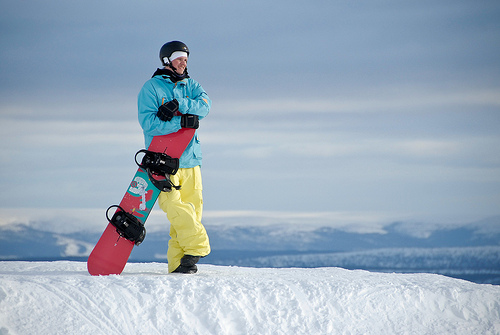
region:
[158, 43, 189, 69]
THE GIRL SI WEARING A WHITE HAT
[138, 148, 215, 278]
THE GIRL IS WEARING SKI PANTS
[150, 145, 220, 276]
THE GIRL'S PANTS ARE YELLOW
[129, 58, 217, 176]
THE GIRL IS WEARING A BLUE JACKET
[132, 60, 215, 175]
THE GIRL IS HOLDING A SNOWBOARD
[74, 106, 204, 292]
THE SNOWBOARD IS PINK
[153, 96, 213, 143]
THE GIRL IS WEARING BLACK GLOVES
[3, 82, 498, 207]
THE CLOUDS ARE LONG AND WHISPY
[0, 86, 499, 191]
THE CLOUDS ARE IN THE SKY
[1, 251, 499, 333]
THE MOUNTAIN IS HIGH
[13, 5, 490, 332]
a snowboarder on top of a mountain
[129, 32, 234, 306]
a person wearing snow gear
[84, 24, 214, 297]
a man holding a pink snowboard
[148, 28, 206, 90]
a person wearing a black helmet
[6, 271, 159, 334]
ski tracks in the snow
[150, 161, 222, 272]
bright yellow snow pants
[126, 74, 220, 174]
a bright blue ski jacket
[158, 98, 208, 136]
a person wearing black gloves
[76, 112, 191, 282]
a bright pink snowboard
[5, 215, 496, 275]
a mountain range in the distance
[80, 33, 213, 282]
Snowboarder on the mountain.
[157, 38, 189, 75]
Black helmet on boarder.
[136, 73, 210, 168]
Blue jacket on the boarder.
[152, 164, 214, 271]
Yellow snow pants on boarder.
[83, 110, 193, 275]
Red snow board being held.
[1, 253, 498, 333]
Snow on the mountain.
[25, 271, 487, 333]
Marks on the snow from the skiiers.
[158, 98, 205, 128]
Black gloves on the snow boarder.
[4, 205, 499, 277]
Mountains in the background.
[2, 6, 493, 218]
Cloudy ski in the background.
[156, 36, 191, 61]
black helmet for female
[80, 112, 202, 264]
red teal white snowboard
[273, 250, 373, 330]
snow mountain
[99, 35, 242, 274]
female snowboarder with snowboard in hand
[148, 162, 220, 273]
female yellow snow pants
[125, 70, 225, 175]
light blue snow jacket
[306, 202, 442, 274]
several mountains with snow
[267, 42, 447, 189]
dark blue and white sky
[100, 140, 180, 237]
two black feet rests for snowboard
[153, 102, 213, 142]
two black snow gloves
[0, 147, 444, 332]
Top of a mountain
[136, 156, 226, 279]
Man wearing yellow pants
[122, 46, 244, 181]
Man wearing blue shirt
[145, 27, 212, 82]
Man wearing helmet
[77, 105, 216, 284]
Man holding red snowboard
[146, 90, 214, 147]
Man wearing black gloves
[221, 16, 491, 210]
Cloudy skies in background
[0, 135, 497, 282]
Mountain sides in background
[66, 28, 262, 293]
Man standing on top of mountain side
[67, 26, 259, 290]
Man smiling